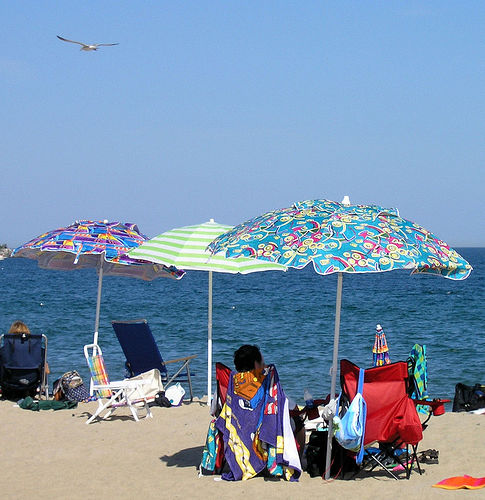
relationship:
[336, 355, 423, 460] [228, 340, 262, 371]
chair next to person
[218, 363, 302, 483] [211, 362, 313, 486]
towel on chair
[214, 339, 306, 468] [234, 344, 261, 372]
person with hair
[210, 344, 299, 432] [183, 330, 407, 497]
people with chair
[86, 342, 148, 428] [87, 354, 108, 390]
chair in back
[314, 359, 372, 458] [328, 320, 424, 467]
bag in seat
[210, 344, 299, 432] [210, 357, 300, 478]
people in chair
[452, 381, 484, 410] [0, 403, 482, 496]
bag on sand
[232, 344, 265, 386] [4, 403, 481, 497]
people enjoying beach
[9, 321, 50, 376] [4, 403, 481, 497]
lady enjoying beach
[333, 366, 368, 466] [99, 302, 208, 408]
bag draped over chair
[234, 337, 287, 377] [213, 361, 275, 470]
person sitting in chair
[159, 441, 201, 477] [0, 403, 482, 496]
shadow on sand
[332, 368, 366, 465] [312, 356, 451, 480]
bag hanging on chair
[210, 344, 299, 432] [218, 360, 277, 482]
people sitting in a chair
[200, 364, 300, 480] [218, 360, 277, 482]
towel hanging on a chair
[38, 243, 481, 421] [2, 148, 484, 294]
water in distance